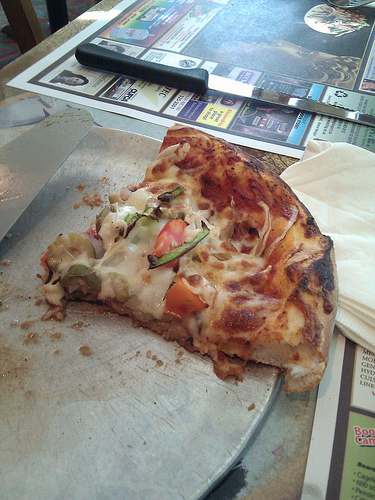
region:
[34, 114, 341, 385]
pizza on a pan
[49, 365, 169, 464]
pan is made of metal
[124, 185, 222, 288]
green peppers on pizza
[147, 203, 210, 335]
tomatoes on pizza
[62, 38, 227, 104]
knife with black handle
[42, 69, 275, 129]
newpaper on table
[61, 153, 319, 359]
thick crust pizza with melted cheese on top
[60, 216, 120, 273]
red onions on pizza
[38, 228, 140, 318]
green olives on the pizza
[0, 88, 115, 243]
metal pizza server on pan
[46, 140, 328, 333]
One slice of pizza.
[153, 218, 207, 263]
The pizza has geen peppers.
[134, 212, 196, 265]
The tomato is red.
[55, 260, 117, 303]
The mushroom is on the pizza.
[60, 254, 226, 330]
The cheese is on the pizza.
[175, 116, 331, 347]
The pizza is cooked.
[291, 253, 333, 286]
Burnt spot on the pizza.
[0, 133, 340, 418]
The pizza is on the plate.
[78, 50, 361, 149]
The knife is on the table.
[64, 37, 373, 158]
The knife has a black handle.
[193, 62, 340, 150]
a knife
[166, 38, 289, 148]
a knife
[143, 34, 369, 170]
a knife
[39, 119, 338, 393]
large slice of cheesy pizza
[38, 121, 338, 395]
pizza full of cheese and toppings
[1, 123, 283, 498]
pizza on round silver pan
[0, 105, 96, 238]
silver spatula next to pizza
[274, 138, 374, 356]
stack of white napkins near pizza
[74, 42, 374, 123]
black handled knife on table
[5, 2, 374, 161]
placemat full of ads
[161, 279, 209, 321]
small red tomato slice on pizza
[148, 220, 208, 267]
slice of green pepper atop pizza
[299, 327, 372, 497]
placemat near pizza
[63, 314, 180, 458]
the tray is silver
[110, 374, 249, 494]
the tray is silver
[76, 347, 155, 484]
the tray is silver